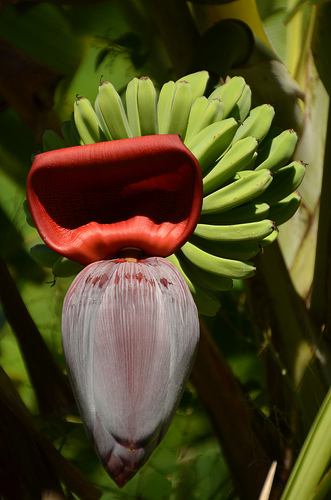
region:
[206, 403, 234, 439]
part of a loine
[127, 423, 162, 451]
edge f a line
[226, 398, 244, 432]
part of a branch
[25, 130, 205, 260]
Large bent over red petal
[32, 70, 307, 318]
Bunch of green bananas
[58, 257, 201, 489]
Unopened purple and red hued bud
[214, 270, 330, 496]
Thin, long green branches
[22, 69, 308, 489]
Bunch of bananas and flower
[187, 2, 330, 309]
Sunlight shining down on green branches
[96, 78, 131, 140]
Unripe banana with brown tip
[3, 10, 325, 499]
Bananas growing in a banana tree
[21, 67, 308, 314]
Large bunch of unripe bananas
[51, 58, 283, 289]
Green Bananas growing on a tree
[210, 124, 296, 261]
Green Bananas growing on a tree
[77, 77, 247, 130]
Green Bananas growing on a tree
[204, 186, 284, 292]
Green Bananas growing on a tree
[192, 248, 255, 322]
Green Bananas growing on a tree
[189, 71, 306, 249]
Green Bananas growing on a tree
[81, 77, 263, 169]
a group of banana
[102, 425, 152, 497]
a buttom part of fruit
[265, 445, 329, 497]
a part of stem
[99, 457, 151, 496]
red color in the fruit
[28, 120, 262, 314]
top part of the banana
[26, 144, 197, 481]
a banana in its early stage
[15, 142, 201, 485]
a banana about to come out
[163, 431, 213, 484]
green laves in the back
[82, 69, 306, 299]
a group of late bananas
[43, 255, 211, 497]
this is a banana flower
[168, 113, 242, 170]
this is a green banana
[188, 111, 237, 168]
this is a green banana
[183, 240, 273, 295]
this is a green banana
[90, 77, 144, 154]
this is a green banana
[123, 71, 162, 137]
this is a green banana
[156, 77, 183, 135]
this is a green banana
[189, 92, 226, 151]
this is a green banana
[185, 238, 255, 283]
green petal on flower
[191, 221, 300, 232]
green petal on flower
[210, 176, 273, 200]
green petal on flower